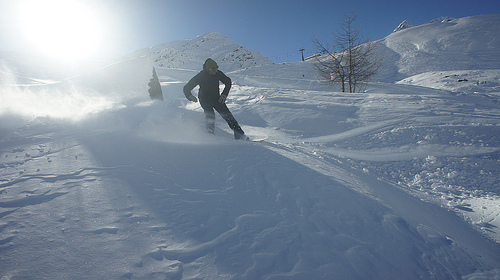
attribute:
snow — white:
[90, 123, 469, 248]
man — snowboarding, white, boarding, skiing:
[172, 58, 269, 151]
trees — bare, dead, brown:
[315, 20, 378, 90]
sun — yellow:
[9, 4, 109, 68]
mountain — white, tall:
[159, 25, 262, 52]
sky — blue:
[183, 1, 290, 36]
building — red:
[305, 49, 321, 62]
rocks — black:
[459, 80, 476, 90]